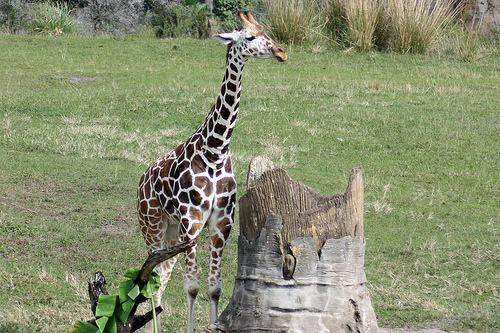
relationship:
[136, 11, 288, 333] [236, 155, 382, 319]
giraffe near stump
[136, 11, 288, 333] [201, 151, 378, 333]
giraffe looks over stump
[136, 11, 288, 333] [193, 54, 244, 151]
giraffe has neck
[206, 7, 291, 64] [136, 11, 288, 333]
head of giraffe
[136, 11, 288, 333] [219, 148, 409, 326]
giraffe near tree trunk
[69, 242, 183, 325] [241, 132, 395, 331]
plant near tree stump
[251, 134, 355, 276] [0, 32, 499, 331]
stump in ground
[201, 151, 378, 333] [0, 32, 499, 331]
stump in ground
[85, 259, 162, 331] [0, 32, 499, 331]
tree stump in ground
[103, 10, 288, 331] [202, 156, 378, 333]
giraffe next to tree trunk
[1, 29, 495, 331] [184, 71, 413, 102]
grass has spots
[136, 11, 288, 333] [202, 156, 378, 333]
giraffe looking on tree trunk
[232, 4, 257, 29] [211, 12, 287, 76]
horn on h head